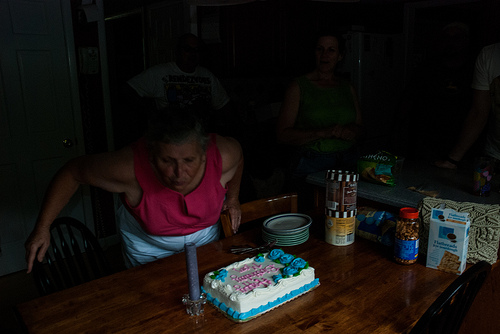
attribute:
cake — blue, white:
[196, 247, 325, 317]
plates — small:
[250, 214, 317, 249]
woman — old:
[24, 112, 268, 264]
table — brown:
[1, 211, 486, 332]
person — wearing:
[98, 114, 283, 259]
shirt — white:
[112, 153, 232, 240]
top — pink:
[128, 166, 279, 243]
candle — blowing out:
[171, 233, 231, 304]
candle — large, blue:
[184, 240, 201, 298]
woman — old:
[26, 122, 244, 253]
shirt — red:
[124, 139, 225, 236]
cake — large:
[198, 245, 323, 325]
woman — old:
[49, 82, 276, 286]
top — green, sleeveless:
[289, 69, 369, 189]